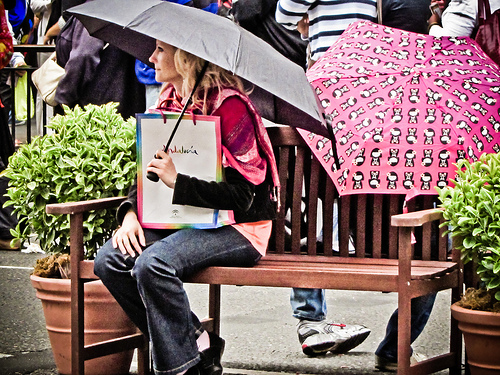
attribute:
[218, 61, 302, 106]
umbrella — black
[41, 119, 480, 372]
bench — brown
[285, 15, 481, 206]
umbrella — pink, black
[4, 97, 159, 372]
plant — potted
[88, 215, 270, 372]
jeans — blue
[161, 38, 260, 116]
hair — blonde, long